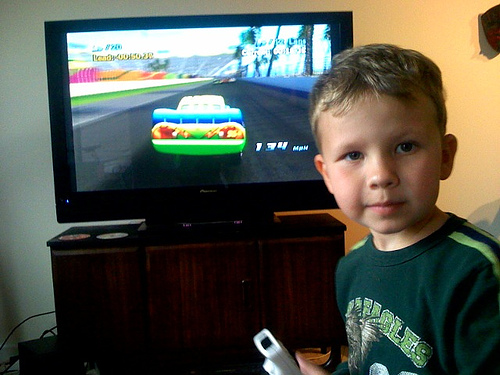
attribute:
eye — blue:
[393, 140, 423, 158]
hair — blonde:
[325, 49, 405, 106]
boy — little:
[297, 39, 472, 279]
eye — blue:
[334, 148, 369, 165]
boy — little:
[242, 33, 497, 370]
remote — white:
[248, 325, 299, 374]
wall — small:
[421, 14, 498, 174]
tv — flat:
[41, 9, 369, 236]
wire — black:
[448, 44, 486, 85]